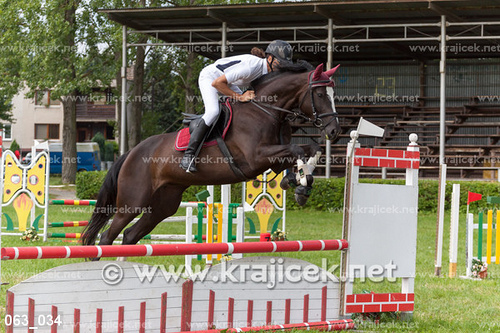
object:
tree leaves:
[5, 7, 91, 96]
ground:
[407, 130, 458, 202]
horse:
[78, 61, 345, 262]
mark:
[325, 84, 341, 126]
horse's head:
[298, 63, 344, 141]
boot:
[179, 117, 209, 172]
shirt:
[209, 53, 270, 90]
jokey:
[178, 38, 295, 173]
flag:
[468, 191, 483, 205]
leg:
[184, 75, 223, 159]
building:
[2, 58, 74, 160]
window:
[34, 122, 61, 139]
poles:
[0, 0, 499, 308]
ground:
[272, 68, 334, 115]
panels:
[0, 257, 341, 332]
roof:
[97, 1, 494, 79]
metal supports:
[112, 6, 497, 171]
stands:
[279, 94, 499, 179]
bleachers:
[97, 0, 499, 179]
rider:
[178, 40, 294, 172]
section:
[452, 112, 485, 146]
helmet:
[264, 40, 294, 73]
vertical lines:
[11, 272, 354, 333]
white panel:
[347, 182, 419, 279]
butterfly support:
[241, 168, 286, 240]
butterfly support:
[0, 140, 52, 242]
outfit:
[185, 54, 266, 126]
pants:
[188, 67, 243, 145]